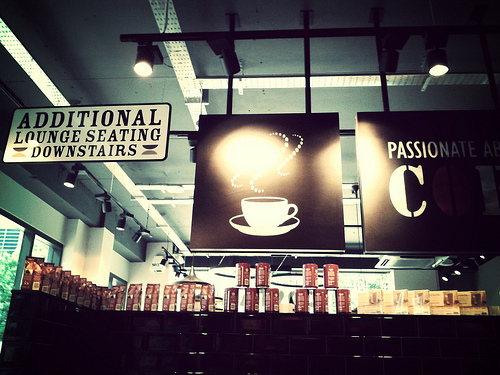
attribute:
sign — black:
[358, 106, 496, 255]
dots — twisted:
[230, 126, 304, 191]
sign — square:
[187, 106, 347, 250]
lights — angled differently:
[93, 189, 145, 250]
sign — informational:
[5, 105, 173, 162]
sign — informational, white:
[0, 99, 175, 168]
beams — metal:
[0, 25, 64, 112]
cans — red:
[226, 265, 358, 315]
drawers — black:
[94, 306, 489, 373]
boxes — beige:
[356, 283, 496, 313]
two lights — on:
[127, 45, 459, 82]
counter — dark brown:
[2, 287, 497, 370]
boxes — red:
[211, 260, 360, 320]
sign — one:
[353, 103, 486, 273]